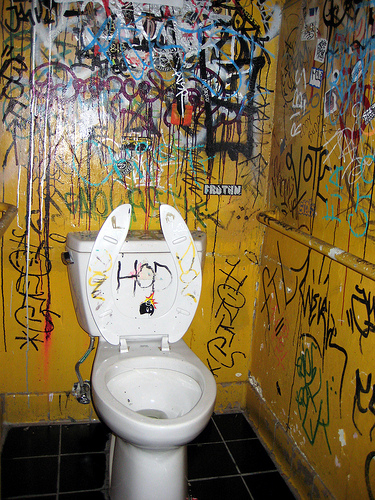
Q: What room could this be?
A: It is a bathroom.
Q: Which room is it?
A: It is a bathroom.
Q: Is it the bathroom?
A: Yes, it is the bathroom.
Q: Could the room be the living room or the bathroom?
A: It is the bathroom.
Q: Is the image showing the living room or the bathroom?
A: It is showing the bathroom.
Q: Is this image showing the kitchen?
A: No, the picture is showing the bathroom.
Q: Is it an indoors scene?
A: Yes, it is indoors.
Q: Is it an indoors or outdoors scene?
A: It is indoors.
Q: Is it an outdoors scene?
A: No, it is indoors.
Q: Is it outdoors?
A: No, it is indoors.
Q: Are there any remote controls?
A: Yes, there is a remote control.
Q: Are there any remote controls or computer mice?
A: Yes, there is a remote control.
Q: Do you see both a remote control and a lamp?
A: No, there is a remote control but no lamps.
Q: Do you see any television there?
A: No, there are no televisions.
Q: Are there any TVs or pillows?
A: No, there are no TVs or pillows.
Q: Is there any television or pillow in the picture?
A: No, there are no televisions or pillows.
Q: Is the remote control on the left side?
A: Yes, the remote control is on the left of the image.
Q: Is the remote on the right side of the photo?
A: No, the remote is on the left of the image.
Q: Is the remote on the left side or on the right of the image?
A: The remote is on the left of the image.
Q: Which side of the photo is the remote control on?
A: The remote control is on the left of the image.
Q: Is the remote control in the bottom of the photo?
A: Yes, the remote control is in the bottom of the image.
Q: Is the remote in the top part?
A: No, the remote is in the bottom of the image.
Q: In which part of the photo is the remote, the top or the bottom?
A: The remote is in the bottom of the image.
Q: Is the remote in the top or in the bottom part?
A: The remote is in the bottom of the image.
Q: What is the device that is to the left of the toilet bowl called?
A: The device is a remote control.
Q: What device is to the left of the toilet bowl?
A: The device is a remote control.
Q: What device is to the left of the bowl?
A: The device is a remote control.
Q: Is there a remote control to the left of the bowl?
A: Yes, there is a remote control to the left of the bowl.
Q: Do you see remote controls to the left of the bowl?
A: Yes, there is a remote control to the left of the bowl.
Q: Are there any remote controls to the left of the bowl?
A: Yes, there is a remote control to the left of the bowl.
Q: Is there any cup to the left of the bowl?
A: No, there is a remote control to the left of the bowl.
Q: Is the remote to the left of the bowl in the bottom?
A: Yes, the remote is to the left of the bowl.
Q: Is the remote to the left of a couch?
A: No, the remote is to the left of the bowl.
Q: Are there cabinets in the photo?
A: No, there are no cabinets.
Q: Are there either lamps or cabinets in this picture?
A: No, there are no cabinets or lamps.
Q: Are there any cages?
A: No, there are no cages.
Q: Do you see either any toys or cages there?
A: No, there are no cages or toys.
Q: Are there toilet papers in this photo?
A: No, there are no toilet papers.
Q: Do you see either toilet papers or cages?
A: No, there are no toilet papers or cages.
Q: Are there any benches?
A: No, there are no benches.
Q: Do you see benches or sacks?
A: No, there are no benches or sacks.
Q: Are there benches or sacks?
A: No, there are no benches or sacks.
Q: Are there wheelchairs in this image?
A: No, there are no wheelchairs.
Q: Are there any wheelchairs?
A: No, there are no wheelchairs.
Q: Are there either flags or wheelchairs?
A: No, there are no wheelchairs or flags.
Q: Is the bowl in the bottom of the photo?
A: Yes, the bowl is in the bottom of the image.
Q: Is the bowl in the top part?
A: No, the bowl is in the bottom of the image.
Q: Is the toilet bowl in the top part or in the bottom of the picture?
A: The bowl is in the bottom of the image.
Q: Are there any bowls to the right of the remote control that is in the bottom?
A: Yes, there is a bowl to the right of the remote.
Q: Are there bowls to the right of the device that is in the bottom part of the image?
A: Yes, there is a bowl to the right of the remote.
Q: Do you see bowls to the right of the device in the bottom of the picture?
A: Yes, there is a bowl to the right of the remote.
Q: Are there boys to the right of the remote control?
A: No, there is a bowl to the right of the remote control.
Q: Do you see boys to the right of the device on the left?
A: No, there is a bowl to the right of the remote control.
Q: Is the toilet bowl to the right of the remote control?
A: Yes, the bowl is to the right of the remote control.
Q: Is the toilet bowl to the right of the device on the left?
A: Yes, the bowl is to the right of the remote control.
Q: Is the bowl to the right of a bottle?
A: No, the bowl is to the right of the remote control.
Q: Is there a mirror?
A: No, there are no mirrors.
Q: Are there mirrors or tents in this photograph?
A: No, there are no mirrors or tents.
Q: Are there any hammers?
A: No, there are no hammers.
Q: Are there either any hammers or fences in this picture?
A: No, there are no hammers or fences.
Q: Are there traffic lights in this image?
A: No, there are no traffic lights.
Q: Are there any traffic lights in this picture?
A: No, there are no traffic lights.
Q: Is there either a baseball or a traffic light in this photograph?
A: No, there are no traffic lights or baseballs.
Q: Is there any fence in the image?
A: No, there are no fences.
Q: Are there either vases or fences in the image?
A: No, there are no fences or vases.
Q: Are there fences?
A: No, there are no fences.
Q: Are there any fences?
A: No, there are no fences.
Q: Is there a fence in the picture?
A: No, there are no fences.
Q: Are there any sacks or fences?
A: No, there are no fences or sacks.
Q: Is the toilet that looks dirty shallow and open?
A: Yes, the toilet is shallow and open.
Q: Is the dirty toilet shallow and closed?
A: No, the toilet is shallow but open.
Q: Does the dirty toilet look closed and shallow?
A: No, the toilet is shallow but open.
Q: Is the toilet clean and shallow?
A: No, the toilet is shallow but dirty.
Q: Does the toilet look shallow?
A: Yes, the toilet is shallow.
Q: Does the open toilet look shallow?
A: Yes, the toilet is shallow.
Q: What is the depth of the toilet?
A: The toilet is shallow.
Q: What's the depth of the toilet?
A: The toilet is shallow.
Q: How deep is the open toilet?
A: The toilet is shallow.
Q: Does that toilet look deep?
A: No, the toilet is shallow.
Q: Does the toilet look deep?
A: No, the toilet is shallow.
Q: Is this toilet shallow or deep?
A: The toilet is shallow.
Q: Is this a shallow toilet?
A: Yes, this is a shallow toilet.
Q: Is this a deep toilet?
A: No, this is a shallow toilet.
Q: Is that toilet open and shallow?
A: Yes, the toilet is open and shallow.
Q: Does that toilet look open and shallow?
A: Yes, the toilet is open and shallow.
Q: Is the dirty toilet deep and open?
A: No, the toilet is open but shallow.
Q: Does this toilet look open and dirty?
A: Yes, the toilet is open and dirty.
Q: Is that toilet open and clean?
A: No, the toilet is open but dirty.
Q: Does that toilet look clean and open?
A: No, the toilet is open but dirty.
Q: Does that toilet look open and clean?
A: No, the toilet is open but dirty.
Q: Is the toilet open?
A: Yes, the toilet is open.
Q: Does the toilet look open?
A: Yes, the toilet is open.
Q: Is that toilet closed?
A: No, the toilet is open.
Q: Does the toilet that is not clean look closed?
A: No, the toilet is open.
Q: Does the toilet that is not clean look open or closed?
A: The toilet is open.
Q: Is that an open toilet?
A: Yes, that is an open toilet.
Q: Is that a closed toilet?
A: No, that is an open toilet.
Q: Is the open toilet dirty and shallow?
A: Yes, the toilet is dirty and shallow.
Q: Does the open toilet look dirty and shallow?
A: Yes, the toilet is dirty and shallow.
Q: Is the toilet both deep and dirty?
A: No, the toilet is dirty but shallow.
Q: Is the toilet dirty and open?
A: Yes, the toilet is dirty and open.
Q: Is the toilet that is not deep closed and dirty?
A: No, the toilet is dirty but open.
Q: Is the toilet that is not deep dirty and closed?
A: No, the toilet is dirty but open.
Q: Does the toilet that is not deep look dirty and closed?
A: No, the toilet is dirty but open.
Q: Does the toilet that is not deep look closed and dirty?
A: No, the toilet is dirty but open.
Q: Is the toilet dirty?
A: Yes, the toilet is dirty.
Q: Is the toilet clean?
A: No, the toilet is dirty.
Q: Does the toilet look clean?
A: No, the toilet is dirty.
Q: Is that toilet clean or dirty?
A: The toilet is dirty.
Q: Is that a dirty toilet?
A: Yes, that is a dirty toilet.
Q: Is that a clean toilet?
A: No, that is a dirty toilet.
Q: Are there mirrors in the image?
A: No, there are no mirrors.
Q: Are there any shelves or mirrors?
A: No, there are no mirrors or shelves.